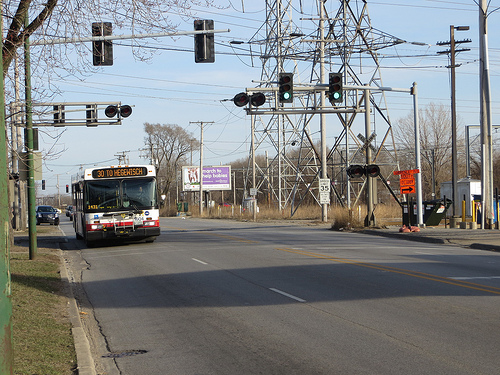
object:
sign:
[393, 169, 419, 194]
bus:
[70, 163, 181, 247]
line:
[266, 284, 307, 305]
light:
[276, 71, 293, 102]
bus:
[79, 158, 164, 245]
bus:
[72, 165, 167, 247]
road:
[79, 219, 500, 374]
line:
[314, 248, 435, 286]